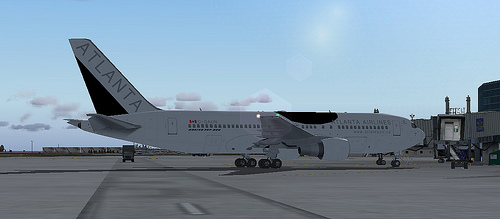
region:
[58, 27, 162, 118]
tail of white plane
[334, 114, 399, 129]
atlanta airlines on plane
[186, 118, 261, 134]
small windows on plane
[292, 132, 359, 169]
engine on side of plane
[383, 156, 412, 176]
wheel on front of plane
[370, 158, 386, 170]
wheel on front of plane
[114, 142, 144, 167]
cargo truck on tarmac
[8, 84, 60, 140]
grey clouds in sky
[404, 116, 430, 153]
nose of plane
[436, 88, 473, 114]
control towers for airport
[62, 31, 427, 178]
Plane is white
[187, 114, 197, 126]
Canadian flag on white plane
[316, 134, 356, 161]
White engine on plane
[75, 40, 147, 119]
Atlanta logo on tail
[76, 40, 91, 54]
Letter A is gray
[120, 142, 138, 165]
Parked van on runway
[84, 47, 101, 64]
Letter T is gray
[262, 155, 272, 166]
Black rubber tire on plane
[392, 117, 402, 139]
White door by cockpit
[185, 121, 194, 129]
Small window on side of plane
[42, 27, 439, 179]
a white commercial airplane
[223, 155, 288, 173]
the wheels of an airplane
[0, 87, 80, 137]
sparse clouds in the sky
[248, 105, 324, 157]
the wings of an airplane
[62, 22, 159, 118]
the logo of an airline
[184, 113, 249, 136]
the windows on an airplane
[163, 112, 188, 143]
an airplanes emergency exit door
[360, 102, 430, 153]
the nose on an airplane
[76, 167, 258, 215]
a runway for the plane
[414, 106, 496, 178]
the loading dock for the plane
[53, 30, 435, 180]
Passenger plane on airport tarmac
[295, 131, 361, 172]
Engine on right side passenger plane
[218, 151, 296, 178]
Landing gear on passenger plane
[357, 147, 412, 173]
Landing gear on front of passenger plane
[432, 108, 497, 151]
Walkway to enter airplane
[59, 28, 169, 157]
Tale of passenger airplane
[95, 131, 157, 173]
Truck on airport tarmac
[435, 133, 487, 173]
Luggage carrying vehicle for airport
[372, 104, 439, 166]
Front of passenger plane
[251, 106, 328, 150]
Right wing of passenger plane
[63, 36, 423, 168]
An Atlanta passenger plane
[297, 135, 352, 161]
A airplane turbine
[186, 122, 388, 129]
Many windows on a passenger plane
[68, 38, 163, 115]
The tail fin of an airplane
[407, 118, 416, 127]
The cockpit of a passenger plane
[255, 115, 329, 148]
The wing of a passenger plane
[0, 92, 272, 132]
Several distant clouds in the sky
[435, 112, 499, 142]
The passenger loading ramp of an airport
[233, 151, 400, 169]
Landing gear of a passenger plane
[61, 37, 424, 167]
A large, white passenger plane